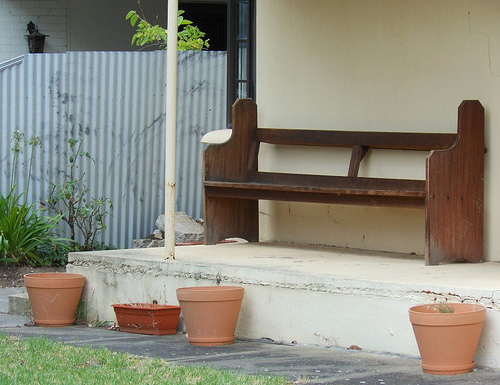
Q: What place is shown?
A: It is a porch.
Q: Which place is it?
A: It is a porch.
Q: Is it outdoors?
A: Yes, it is outdoors.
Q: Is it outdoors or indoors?
A: It is outdoors.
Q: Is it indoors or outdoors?
A: It is outdoors.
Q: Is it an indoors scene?
A: No, it is outdoors.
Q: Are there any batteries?
A: No, there are no batteries.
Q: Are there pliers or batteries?
A: No, there are no batteries or pliers.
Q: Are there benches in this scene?
A: Yes, there is a bench.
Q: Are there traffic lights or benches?
A: Yes, there is a bench.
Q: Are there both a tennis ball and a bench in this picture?
A: No, there is a bench but no tennis balls.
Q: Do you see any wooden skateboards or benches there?
A: Yes, there is a wood bench.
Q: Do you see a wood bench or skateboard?
A: Yes, there is a wood bench.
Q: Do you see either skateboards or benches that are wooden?
A: Yes, the bench is wooden.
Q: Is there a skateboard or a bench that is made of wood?
A: Yes, the bench is made of wood.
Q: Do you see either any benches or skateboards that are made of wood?
A: Yes, the bench is made of wood.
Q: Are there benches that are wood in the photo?
A: Yes, there is a wood bench.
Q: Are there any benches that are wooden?
A: Yes, there is a bench that is wooden.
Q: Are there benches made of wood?
A: Yes, there is a bench that is made of wood.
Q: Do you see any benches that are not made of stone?
A: Yes, there is a bench that is made of wood.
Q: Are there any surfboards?
A: No, there are no surfboards.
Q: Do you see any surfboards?
A: No, there are no surfboards.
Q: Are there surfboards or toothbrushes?
A: No, there are no surfboards or toothbrushes.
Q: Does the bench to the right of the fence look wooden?
A: Yes, the bench is wooden.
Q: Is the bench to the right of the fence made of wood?
A: Yes, the bench is made of wood.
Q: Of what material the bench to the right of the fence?
A: The bench is made of wood.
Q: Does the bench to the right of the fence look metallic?
A: No, the bench is wooden.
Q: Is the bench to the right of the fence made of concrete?
A: No, the bench is made of wood.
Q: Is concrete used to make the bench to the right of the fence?
A: No, the bench is made of wood.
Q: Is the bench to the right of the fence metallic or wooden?
A: The bench is wooden.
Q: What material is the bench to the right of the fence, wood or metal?
A: The bench is made of wood.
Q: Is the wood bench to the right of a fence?
A: Yes, the bench is to the right of a fence.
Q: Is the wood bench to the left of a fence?
A: No, the bench is to the right of a fence.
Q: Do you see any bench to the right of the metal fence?
A: Yes, there is a bench to the right of the fence.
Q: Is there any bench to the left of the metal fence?
A: No, the bench is to the right of the fence.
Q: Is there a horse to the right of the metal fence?
A: No, there is a bench to the right of the fence.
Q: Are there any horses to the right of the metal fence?
A: No, there is a bench to the right of the fence.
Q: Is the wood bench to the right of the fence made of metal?
A: Yes, the bench is to the right of the fence.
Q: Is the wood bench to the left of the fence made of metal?
A: No, the bench is to the right of the fence.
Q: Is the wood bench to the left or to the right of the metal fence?
A: The bench is to the right of the fence.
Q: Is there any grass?
A: Yes, there is grass.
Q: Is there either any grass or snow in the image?
A: Yes, there is grass.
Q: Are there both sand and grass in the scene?
A: No, there is grass but no sand.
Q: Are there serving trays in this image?
A: No, there are no serving trays.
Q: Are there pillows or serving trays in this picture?
A: No, there are no serving trays or pillows.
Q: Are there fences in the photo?
A: Yes, there is a fence.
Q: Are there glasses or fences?
A: Yes, there is a fence.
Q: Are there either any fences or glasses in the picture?
A: Yes, there is a fence.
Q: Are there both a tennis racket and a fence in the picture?
A: No, there is a fence but no rackets.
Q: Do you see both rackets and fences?
A: No, there is a fence but no rackets.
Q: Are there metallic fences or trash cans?
A: Yes, there is a metal fence.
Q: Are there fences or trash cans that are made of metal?
A: Yes, the fence is made of metal.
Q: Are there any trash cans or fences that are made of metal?
A: Yes, the fence is made of metal.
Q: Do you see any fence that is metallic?
A: Yes, there is a metal fence.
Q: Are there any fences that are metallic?
A: Yes, there is a fence that is metallic.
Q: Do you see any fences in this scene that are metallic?
A: Yes, there is a fence that is metallic.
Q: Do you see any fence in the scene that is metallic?
A: Yes, there is a fence that is metallic.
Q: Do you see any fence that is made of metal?
A: Yes, there is a fence that is made of metal.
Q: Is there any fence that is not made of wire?
A: Yes, there is a fence that is made of metal.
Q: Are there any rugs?
A: No, there are no rugs.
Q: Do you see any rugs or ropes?
A: No, there are no rugs or ropes.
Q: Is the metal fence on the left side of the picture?
A: Yes, the fence is on the left of the image.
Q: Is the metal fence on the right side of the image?
A: No, the fence is on the left of the image.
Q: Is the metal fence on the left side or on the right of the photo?
A: The fence is on the left of the image.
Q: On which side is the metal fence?
A: The fence is on the left of the image.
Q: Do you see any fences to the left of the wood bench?
A: Yes, there is a fence to the left of the bench.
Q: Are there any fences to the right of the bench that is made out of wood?
A: No, the fence is to the left of the bench.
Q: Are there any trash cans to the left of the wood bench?
A: No, there is a fence to the left of the bench.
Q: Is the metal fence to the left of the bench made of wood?
A: Yes, the fence is to the left of the bench.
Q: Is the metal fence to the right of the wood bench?
A: No, the fence is to the left of the bench.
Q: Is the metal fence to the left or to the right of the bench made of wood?
A: The fence is to the left of the bench.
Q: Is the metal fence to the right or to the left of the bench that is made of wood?
A: The fence is to the left of the bench.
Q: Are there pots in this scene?
A: Yes, there is a pot.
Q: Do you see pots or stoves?
A: Yes, there is a pot.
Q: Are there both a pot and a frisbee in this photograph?
A: No, there is a pot but no frisbees.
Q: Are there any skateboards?
A: No, there are no skateboards.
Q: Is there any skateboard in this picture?
A: No, there are no skateboards.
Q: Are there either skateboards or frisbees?
A: No, there are no skateboards or frisbees.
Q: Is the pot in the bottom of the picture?
A: Yes, the pot is in the bottom of the image.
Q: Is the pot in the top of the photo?
A: No, the pot is in the bottom of the image.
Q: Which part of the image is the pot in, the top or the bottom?
A: The pot is in the bottom of the image.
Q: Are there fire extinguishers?
A: No, there are no fire extinguishers.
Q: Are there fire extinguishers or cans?
A: No, there are no fire extinguishers or cans.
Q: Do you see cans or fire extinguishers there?
A: No, there are no fire extinguishers or cans.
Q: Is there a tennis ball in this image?
A: No, there are no tennis balls.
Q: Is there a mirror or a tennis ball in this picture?
A: No, there are no tennis balls or mirrors.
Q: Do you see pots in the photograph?
A: Yes, there is a pot.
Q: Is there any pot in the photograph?
A: Yes, there is a pot.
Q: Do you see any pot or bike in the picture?
A: Yes, there is a pot.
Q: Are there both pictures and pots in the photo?
A: No, there is a pot but no pictures.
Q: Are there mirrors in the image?
A: No, there are no mirrors.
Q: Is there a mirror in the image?
A: No, there are no mirrors.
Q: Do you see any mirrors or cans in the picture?
A: No, there are no mirrors or cans.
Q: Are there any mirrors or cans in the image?
A: No, there are no mirrors or cans.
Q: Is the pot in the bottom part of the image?
A: Yes, the pot is in the bottom of the image.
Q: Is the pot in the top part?
A: No, the pot is in the bottom of the image.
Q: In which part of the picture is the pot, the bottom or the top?
A: The pot is in the bottom of the image.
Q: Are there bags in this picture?
A: No, there are no bags.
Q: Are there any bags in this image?
A: No, there are no bags.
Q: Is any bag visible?
A: No, there are no bags.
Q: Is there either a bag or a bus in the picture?
A: No, there are no bags or buses.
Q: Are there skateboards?
A: No, there are no skateboards.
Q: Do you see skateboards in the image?
A: No, there are no skateboards.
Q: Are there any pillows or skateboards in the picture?
A: No, there are no skateboards or pillows.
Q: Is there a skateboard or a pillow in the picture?
A: No, there are no skateboards or pillows.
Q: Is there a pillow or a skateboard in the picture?
A: No, there are no skateboards or pillows.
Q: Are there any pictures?
A: No, there are no pictures.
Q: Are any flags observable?
A: No, there are no flags.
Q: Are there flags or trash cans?
A: No, there are no flags or trash cans.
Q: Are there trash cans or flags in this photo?
A: No, there are no flags or trash cans.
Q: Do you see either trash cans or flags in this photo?
A: No, there are no flags or trash cans.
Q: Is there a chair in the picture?
A: No, there are no chairs.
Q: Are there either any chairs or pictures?
A: No, there are no chairs or pictures.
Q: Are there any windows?
A: Yes, there is a window.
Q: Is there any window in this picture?
A: Yes, there is a window.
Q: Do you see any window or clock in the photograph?
A: Yes, there is a window.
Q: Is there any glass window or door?
A: Yes, there is a glass window.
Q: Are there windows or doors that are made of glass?
A: Yes, the window is made of glass.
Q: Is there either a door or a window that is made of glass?
A: Yes, the window is made of glass.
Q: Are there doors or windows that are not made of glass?
A: No, there is a window but it is made of glass.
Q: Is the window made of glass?
A: Yes, the window is made of glass.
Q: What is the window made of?
A: The window is made of glass.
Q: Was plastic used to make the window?
A: No, the window is made of glass.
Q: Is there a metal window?
A: No, there is a window but it is made of glass.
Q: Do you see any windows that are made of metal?
A: No, there is a window but it is made of glass.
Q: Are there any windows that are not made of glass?
A: No, there is a window but it is made of glass.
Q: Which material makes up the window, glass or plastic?
A: The window is made of glass.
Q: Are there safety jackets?
A: No, there are no safety jackets.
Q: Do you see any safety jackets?
A: No, there are no safety jackets.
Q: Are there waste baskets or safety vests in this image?
A: No, there are no safety vests or waste baskets.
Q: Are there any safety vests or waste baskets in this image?
A: No, there are no safety vests or waste baskets.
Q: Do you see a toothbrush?
A: No, there are no toothbrushes.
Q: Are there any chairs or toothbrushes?
A: No, there are no toothbrushes or chairs.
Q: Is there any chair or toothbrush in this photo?
A: No, there are no toothbrushes or chairs.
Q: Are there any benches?
A: Yes, there is a bench.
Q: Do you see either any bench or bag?
A: Yes, there is a bench.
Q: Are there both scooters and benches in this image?
A: No, there is a bench but no scooters.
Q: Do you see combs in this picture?
A: No, there are no combs.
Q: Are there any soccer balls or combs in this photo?
A: No, there are no combs or soccer balls.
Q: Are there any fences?
A: Yes, there is a fence.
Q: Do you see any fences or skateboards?
A: Yes, there is a fence.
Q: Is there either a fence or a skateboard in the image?
A: Yes, there is a fence.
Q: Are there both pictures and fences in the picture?
A: No, there is a fence but no pictures.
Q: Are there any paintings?
A: No, there are no paintings.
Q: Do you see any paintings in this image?
A: No, there are no paintings.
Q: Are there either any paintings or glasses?
A: No, there are no paintings or glasses.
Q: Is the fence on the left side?
A: Yes, the fence is on the left of the image.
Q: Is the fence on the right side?
A: No, the fence is on the left of the image.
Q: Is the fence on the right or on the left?
A: The fence is on the left of the image.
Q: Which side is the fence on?
A: The fence is on the left of the image.